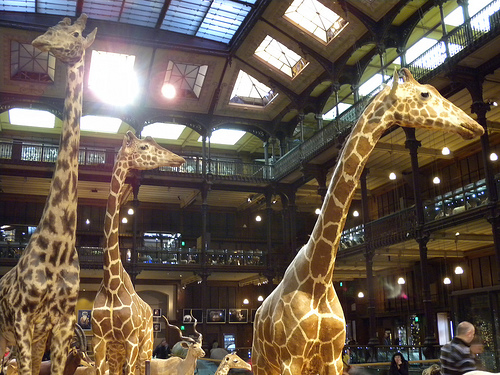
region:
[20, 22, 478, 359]
There are three giraffe statues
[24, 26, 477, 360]
The statues are standing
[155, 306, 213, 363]
The statue has long horns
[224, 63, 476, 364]
Giraffe is yellow with brown spots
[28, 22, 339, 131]
The ceiling has many skylights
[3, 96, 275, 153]
There are arches along the third floor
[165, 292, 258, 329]
Row of pictures on the wall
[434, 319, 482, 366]
Man wearing a striped shirt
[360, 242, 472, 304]
Small lights hang from the ceiling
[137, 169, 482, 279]
Black railing with glass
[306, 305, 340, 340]
A giraffe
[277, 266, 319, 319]
A giraffe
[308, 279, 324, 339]
A giraffe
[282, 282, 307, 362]
A giraffe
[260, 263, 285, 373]
A giraffe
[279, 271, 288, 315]
A giraffe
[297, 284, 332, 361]
A giraffe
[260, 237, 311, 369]
A giraffe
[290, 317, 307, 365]
A giraffe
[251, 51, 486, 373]
tall giraffe looking right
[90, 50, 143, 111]
sunlight coming from window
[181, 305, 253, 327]
animal portraits on wall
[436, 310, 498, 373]
older man walking by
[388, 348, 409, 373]
woman sitting down with black shirt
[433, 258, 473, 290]
lights hanging from ceiling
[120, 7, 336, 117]
museum ceiling with sunlight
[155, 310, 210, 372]
deer with large antlers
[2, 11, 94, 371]
lifesize giraffe looking left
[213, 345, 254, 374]
baby giraffe's head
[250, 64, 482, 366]
giraffe standing in building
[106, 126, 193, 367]
giraffe standing in building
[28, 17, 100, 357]
giraffe standing in building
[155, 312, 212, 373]
gazelle standing in building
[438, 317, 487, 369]
man wearing striped shirt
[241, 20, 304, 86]
window in the ceiling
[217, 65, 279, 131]
window in the ceiling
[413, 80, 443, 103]
eye on the giraffe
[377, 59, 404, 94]
ear on the giraffe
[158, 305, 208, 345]
horns on the gazelle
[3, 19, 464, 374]
these are giraffe sculptures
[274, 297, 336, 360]
the sculptures are shiny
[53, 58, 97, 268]
the neck is tall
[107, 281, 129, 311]
the sculptures are brown in color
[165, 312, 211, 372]
this is an impala sculpture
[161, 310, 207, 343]
these are the horns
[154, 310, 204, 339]
the horns are sharp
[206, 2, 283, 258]
this is a building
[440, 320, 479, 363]
this is a man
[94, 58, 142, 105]
the light is bright